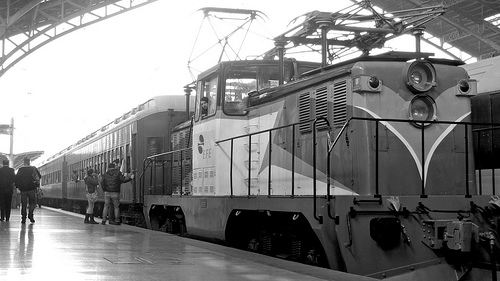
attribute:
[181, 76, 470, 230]
train — huge, black, white, big, moving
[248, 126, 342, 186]
rail — black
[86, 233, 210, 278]
platform — grey, black